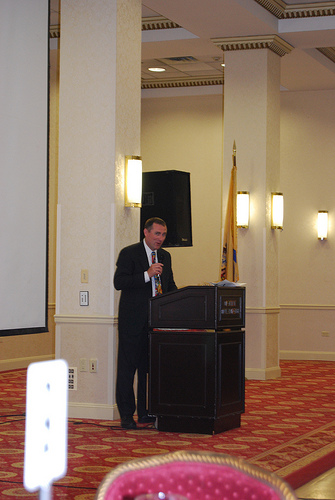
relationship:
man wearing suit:
[102, 217, 183, 440] [112, 243, 179, 430]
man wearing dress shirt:
[102, 217, 183, 440] [142, 238, 164, 297]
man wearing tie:
[111, 217, 179, 431] [141, 246, 168, 296]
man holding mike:
[111, 217, 179, 431] [148, 255, 170, 283]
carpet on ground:
[256, 376, 327, 454] [296, 461, 333, 498]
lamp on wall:
[119, 153, 149, 218] [61, 104, 121, 243]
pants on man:
[119, 324, 156, 436] [111, 217, 179, 431]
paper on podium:
[211, 274, 253, 289] [154, 284, 250, 444]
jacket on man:
[113, 245, 178, 301] [111, 217, 179, 431]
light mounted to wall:
[314, 204, 331, 245] [275, 87, 330, 359]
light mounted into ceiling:
[146, 65, 168, 73] [50, 2, 333, 95]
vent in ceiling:
[160, 53, 200, 70] [50, 2, 333, 95]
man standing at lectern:
[111, 217, 179, 431] [145, 282, 246, 434]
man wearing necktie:
[111, 217, 179, 431] [149, 251, 163, 294]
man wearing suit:
[111, 217, 179, 431] [112, 243, 179, 430]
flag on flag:
[215, 165, 240, 284] [218, 137, 239, 285]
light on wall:
[316, 210, 327, 242] [279, 162, 331, 348]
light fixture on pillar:
[271, 187, 285, 230] [234, 163, 284, 382]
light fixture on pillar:
[234, 187, 253, 230] [234, 163, 284, 382]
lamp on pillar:
[124, 155, 143, 208] [47, 1, 145, 421]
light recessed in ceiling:
[146, 64, 169, 79] [50, 31, 333, 83]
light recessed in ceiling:
[216, 61, 225, 70] [50, 31, 333, 83]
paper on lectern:
[209, 279, 247, 289] [145, 282, 246, 434]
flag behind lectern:
[213, 137, 241, 285] [147, 284, 246, 435]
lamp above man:
[124, 155, 143, 208] [143, 282, 249, 437]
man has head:
[111, 217, 179, 431] [140, 213, 169, 251]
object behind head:
[140, 167, 193, 251] [140, 213, 169, 251]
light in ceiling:
[146, 65, 168, 73] [50, 5, 333, 84]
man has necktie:
[111, 217, 179, 431] [151, 251, 162, 296]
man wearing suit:
[111, 217, 179, 431] [108, 238, 181, 420]